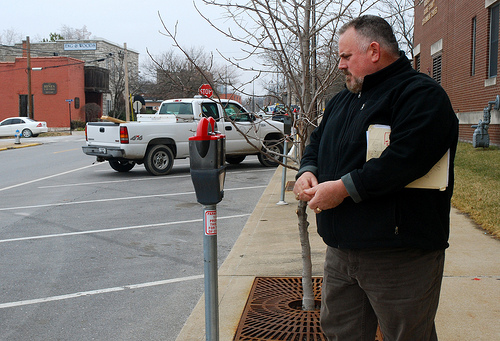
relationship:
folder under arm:
[351, 115, 469, 197] [345, 102, 440, 199]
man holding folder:
[277, 20, 480, 311] [351, 115, 469, 197]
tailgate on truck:
[84, 120, 125, 150] [81, 97, 285, 173]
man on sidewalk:
[277, 20, 480, 311] [168, 120, 493, 339]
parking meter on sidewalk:
[188, 120, 226, 340] [168, 120, 493, 339]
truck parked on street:
[81, 97, 285, 173] [0, 106, 284, 339]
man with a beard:
[277, 20, 480, 311] [345, 78, 370, 98]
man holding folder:
[277, 20, 480, 311] [363, 120, 453, 191]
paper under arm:
[446, 126, 452, 186] [342, 81, 455, 206]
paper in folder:
[446, 126, 452, 186] [363, 120, 453, 191]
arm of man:
[342, 81, 455, 206] [277, 20, 480, 311]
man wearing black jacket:
[277, 20, 480, 311] [296, 51, 462, 252]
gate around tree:
[228, 270, 411, 340] [150, 2, 420, 329]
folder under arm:
[351, 115, 469, 197] [298, 65, 457, 234]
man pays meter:
[277, 20, 480, 311] [190, 115, 231, 205]